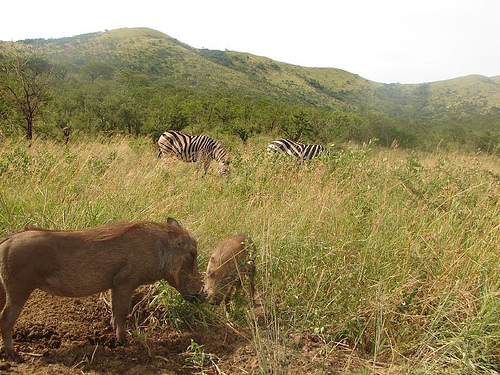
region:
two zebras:
[150, 119, 367, 186]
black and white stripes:
[271, 134, 333, 164]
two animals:
[0, 209, 280, 349]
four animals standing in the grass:
[2, 110, 407, 353]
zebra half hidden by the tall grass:
[266, 136, 353, 181]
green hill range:
[13, 26, 497, 136]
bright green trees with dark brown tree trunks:
[6, 59, 388, 146]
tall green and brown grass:
[4, 144, 493, 358]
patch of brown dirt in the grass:
[29, 297, 116, 361]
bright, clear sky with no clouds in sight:
[16, 5, 495, 80]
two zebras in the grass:
[148, 118, 343, 195]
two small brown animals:
[6, 213, 274, 355]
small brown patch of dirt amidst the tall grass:
[7, 299, 168, 374]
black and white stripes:
[268, 141, 320, 158]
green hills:
[17, 22, 498, 129]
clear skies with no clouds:
[3, 4, 499, 81]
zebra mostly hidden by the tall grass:
[268, 138, 347, 181]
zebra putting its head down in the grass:
[157, 127, 239, 186]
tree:
[6, 77, 48, 143]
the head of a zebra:
[211, 155, 238, 181]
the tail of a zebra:
[149, 126, 166, 154]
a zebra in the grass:
[148, 125, 231, 181]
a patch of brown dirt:
[1, 287, 357, 373]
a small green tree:
[0, 48, 75, 142]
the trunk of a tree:
[22, 112, 39, 145]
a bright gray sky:
[0, 0, 499, 86]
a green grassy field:
[1, 132, 498, 373]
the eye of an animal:
[185, 245, 199, 262]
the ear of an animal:
[163, 212, 185, 230]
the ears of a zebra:
[218, 156, 233, 166]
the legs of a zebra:
[189, 155, 216, 180]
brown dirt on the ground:
[1, 283, 388, 373]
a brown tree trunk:
[18, 108, 38, 138]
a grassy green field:
[1, 134, 499, 374]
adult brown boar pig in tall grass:
[2, 213, 204, 354]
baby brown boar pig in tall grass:
[206, 231, 260, 312]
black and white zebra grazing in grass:
[150, 126, 233, 177]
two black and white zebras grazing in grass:
[153, 128, 333, 179]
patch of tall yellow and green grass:
[301, 191, 472, 324]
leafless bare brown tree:
[6, 74, 52, 141]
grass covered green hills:
[1, 24, 496, 148]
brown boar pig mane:
[28, 219, 185, 240]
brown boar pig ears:
[160, 213, 188, 253]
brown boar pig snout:
[170, 268, 207, 307]